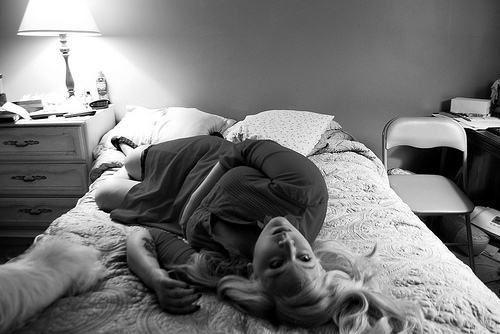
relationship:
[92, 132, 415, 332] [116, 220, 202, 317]
woman has arm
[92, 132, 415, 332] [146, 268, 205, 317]
woman has hand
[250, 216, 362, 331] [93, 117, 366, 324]
head woman on woman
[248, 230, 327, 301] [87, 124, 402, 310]
eyes/woman on woman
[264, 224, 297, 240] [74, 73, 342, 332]
mouth on woman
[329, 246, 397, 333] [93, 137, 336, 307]
hair on woman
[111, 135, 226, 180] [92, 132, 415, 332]
leg on woman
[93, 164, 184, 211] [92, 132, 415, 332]
leg on woman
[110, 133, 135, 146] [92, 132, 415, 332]
shoe on woman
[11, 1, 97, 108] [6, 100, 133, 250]
lamp on stand